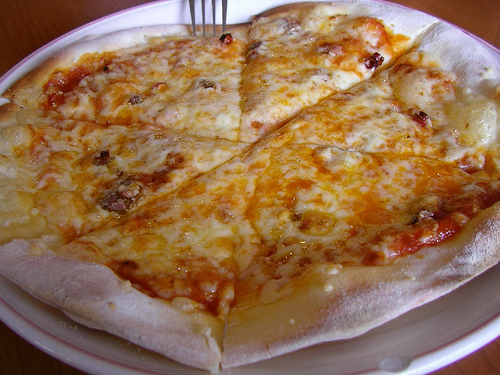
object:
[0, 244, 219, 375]
crust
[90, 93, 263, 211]
cheese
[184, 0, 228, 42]
fork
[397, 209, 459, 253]
sauce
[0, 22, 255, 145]
slice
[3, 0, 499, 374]
pizza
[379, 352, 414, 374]
chip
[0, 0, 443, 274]
half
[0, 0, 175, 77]
border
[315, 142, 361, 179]
bubble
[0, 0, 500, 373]
table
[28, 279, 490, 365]
shadow